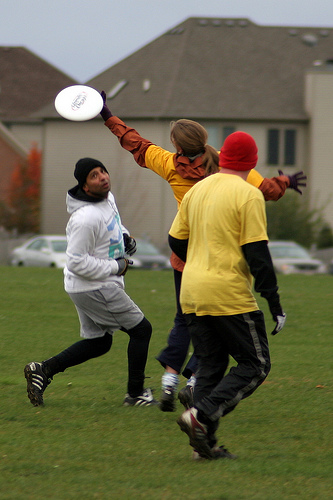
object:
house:
[26, 15, 332, 258]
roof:
[0, 44, 81, 125]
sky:
[0, 0, 333, 85]